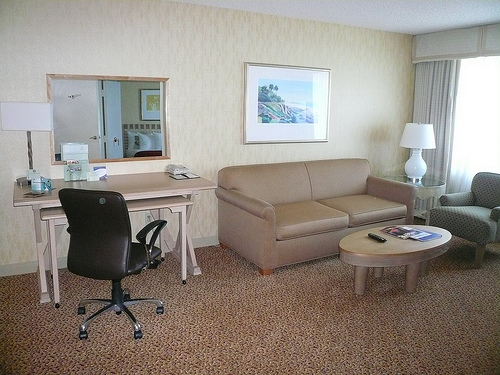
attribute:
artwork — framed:
[238, 60, 329, 143]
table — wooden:
[331, 226, 460, 298]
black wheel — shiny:
[125, 320, 147, 344]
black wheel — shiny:
[150, 298, 170, 316]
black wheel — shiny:
[72, 326, 93, 344]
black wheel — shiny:
[71, 301, 92, 318]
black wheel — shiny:
[120, 288, 134, 306]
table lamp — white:
[398, 122, 435, 179]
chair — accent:
[423, 169, 498, 269]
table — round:
[387, 168, 446, 223]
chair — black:
[39, 175, 179, 343]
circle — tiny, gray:
[97, 197, 107, 204]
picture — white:
[239, 57, 331, 145]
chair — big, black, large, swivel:
[58, 187, 168, 337]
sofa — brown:
[209, 157, 421, 299]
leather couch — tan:
[213, 151, 440, 281]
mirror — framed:
[46, 72, 170, 168]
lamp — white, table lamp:
[393, 125, 434, 179]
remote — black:
[369, 227, 386, 248]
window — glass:
[448, 54, 498, 189]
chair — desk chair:
[28, 168, 193, 370]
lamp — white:
[398, 122, 436, 180]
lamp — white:
[1, 103, 56, 184]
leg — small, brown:
[256, 266, 278, 278]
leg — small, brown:
[216, 236, 229, 252]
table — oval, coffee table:
[326, 216, 464, 278]